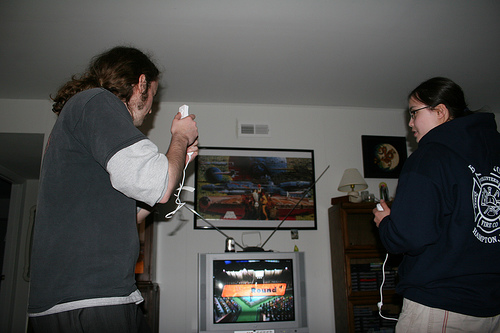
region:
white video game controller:
[173, 101, 205, 166]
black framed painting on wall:
[193, 140, 320, 236]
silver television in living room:
[189, 243, 310, 331]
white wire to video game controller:
[375, 248, 400, 323]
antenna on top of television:
[180, 156, 335, 253]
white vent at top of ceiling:
[230, 114, 275, 140]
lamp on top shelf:
[330, 165, 370, 203]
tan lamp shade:
[332, 165, 372, 195]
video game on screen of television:
[210, 258, 297, 324]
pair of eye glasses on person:
[401, 104, 434, 119]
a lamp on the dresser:
[335, 164, 368, 201]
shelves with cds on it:
[322, 201, 459, 329]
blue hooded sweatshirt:
[378, 110, 498, 310]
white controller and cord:
[168, 99, 201, 226]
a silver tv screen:
[195, 248, 314, 330]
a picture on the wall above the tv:
[191, 141, 319, 236]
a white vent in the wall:
[234, 116, 274, 140]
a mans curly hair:
[47, 44, 167, 109]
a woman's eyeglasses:
[407, 104, 429, 118]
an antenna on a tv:
[177, 163, 331, 253]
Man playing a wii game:
[26, 44, 195, 331]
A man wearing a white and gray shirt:
[27, 84, 171, 314]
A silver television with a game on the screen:
[198, 251, 308, 332]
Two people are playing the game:
[7, 46, 494, 332]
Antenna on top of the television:
[165, 164, 353, 252]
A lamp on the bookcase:
[340, 168, 369, 201]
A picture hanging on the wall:
[191, 150, 319, 230]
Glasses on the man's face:
[405, 102, 433, 118]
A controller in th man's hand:
[175, 104, 198, 159]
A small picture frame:
[360, 133, 408, 178]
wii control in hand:
[168, 96, 198, 153]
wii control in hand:
[161, 93, 214, 181]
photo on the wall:
[186, 144, 319, 240]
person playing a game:
[369, 75, 463, 332]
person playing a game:
[2, 70, 177, 322]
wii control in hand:
[356, 196, 396, 255]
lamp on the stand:
[317, 153, 362, 198]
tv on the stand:
[191, 242, 306, 331]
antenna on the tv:
[212, 181, 294, 259]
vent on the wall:
[230, 118, 277, 133]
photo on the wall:
[340, 122, 398, 186]